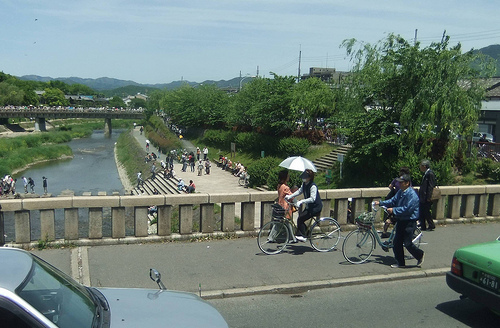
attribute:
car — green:
[444, 236, 499, 321]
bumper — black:
[446, 271, 500, 311]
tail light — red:
[450, 258, 463, 277]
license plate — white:
[476, 275, 498, 295]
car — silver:
[1, 247, 231, 327]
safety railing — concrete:
[0, 183, 500, 249]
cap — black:
[395, 174, 412, 183]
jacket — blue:
[379, 189, 421, 223]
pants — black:
[392, 220, 424, 265]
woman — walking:
[268, 155, 316, 242]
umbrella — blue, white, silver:
[277, 155, 318, 187]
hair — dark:
[276, 169, 288, 186]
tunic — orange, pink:
[274, 186, 297, 222]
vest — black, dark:
[301, 185, 322, 211]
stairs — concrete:
[129, 168, 195, 194]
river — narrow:
[1, 128, 135, 242]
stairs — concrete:
[312, 142, 354, 174]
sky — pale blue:
[1, 1, 499, 85]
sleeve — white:
[295, 183, 318, 209]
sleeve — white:
[289, 183, 305, 198]